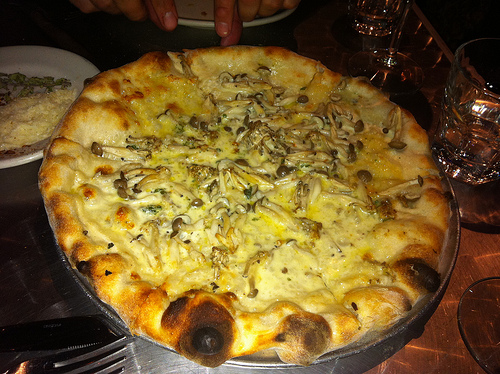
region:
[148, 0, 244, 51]
A person finger touching the pizza.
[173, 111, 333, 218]
Mushrooms on top of the pizza.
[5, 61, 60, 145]
Food on the plate.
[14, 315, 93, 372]
Fork and knife on the countertop.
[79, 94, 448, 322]
A pia in the pan.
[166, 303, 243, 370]
The crust is burnt.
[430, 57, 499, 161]
A glass next to the pan.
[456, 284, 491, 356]
A clear plate on the table.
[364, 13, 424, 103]
A wine glass on the table.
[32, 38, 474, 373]
A large cheesy pizza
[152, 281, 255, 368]
A burnt spot on the pizza crust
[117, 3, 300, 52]
Fingers going to grab the pizza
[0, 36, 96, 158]
White plate filled with food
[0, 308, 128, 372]
A fork and a knife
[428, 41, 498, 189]
A clear drinking glass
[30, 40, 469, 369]
Silver tray holding pizza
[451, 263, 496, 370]
Clear glass plate next to pizza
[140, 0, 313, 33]
A round white plate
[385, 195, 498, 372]
A brown wooden table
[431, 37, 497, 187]
clear drinking glass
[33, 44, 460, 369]
pizza with cheese on it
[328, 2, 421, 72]
glass on the table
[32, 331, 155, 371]
a silver fork ont he table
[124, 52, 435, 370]
melted cheese on the pizza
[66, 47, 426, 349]
a quiche ready to eat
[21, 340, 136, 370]
an eating utensil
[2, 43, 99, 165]
a round white plate on a table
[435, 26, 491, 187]
a glass for drinking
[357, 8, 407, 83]
a glass for drinking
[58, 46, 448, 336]
a nicely browned crust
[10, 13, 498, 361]
a table top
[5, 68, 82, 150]
food on a plate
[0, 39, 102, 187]
The food bowl to the left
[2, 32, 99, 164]
A food bowl to the left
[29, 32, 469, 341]
The pizza on the platter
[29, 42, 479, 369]
A pizza on the platter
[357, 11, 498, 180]
The glasses to the right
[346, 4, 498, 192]
A set of glasses to the right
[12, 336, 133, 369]
The silver fork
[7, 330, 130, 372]
A silver fork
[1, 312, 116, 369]
the silver knife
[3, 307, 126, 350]
A silver knife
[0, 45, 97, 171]
A round white plate.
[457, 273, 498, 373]
A clear round plate.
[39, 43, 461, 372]
A large silver pan with round food inside it.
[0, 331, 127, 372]
A silver fork end.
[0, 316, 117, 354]
A dark butter knife beside a fork.